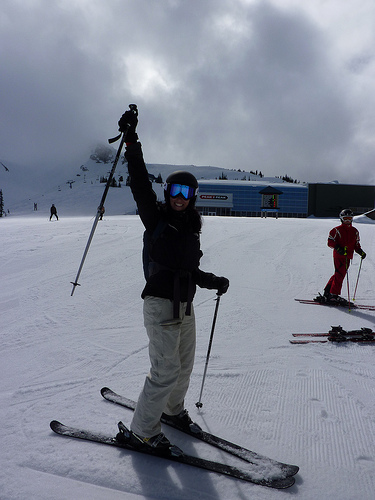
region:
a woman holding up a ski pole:
[43, 90, 261, 398]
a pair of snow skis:
[47, 385, 314, 495]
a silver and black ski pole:
[59, 125, 135, 304]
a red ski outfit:
[313, 203, 371, 307]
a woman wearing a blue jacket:
[122, 146, 241, 313]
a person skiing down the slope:
[45, 199, 70, 254]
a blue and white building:
[206, 179, 309, 218]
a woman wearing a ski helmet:
[158, 168, 199, 210]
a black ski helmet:
[162, 168, 203, 186]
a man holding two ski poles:
[321, 208, 369, 307]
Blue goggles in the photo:
[162, 182, 196, 195]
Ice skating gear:
[50, 384, 314, 494]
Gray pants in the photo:
[127, 301, 199, 438]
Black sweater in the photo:
[143, 205, 202, 296]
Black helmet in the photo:
[165, 161, 205, 187]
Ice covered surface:
[262, 372, 337, 433]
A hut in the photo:
[258, 179, 282, 219]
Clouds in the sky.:
[224, 61, 340, 132]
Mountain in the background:
[53, 124, 114, 208]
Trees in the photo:
[255, 167, 301, 183]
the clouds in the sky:
[0, 0, 373, 188]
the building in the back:
[128, 178, 374, 221]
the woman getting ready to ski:
[49, 102, 300, 488]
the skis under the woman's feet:
[50, 385, 299, 487]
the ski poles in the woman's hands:
[70, 103, 221, 410]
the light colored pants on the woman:
[129, 294, 195, 438]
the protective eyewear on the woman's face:
[162, 182, 196, 199]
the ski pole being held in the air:
[69, 103, 138, 295]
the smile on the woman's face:
[174, 201, 183, 207]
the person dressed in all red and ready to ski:
[294, 207, 374, 312]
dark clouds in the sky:
[6, 3, 369, 100]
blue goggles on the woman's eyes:
[166, 181, 197, 200]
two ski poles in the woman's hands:
[68, 103, 229, 410]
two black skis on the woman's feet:
[48, 386, 299, 489]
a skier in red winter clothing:
[293, 208, 374, 310]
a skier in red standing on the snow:
[294, 208, 374, 312]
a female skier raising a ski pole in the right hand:
[49, 103, 300, 490]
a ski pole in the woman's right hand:
[195, 275, 229, 409]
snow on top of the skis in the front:
[218, 438, 299, 488]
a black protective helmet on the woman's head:
[162, 169, 200, 204]